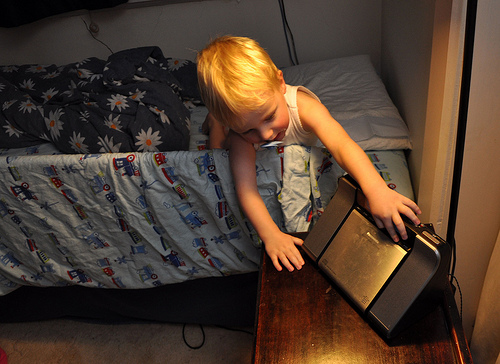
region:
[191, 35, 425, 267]
Blond haired child reaching out from bed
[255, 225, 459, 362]
Wooden night table next to the bed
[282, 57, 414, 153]
White pillow on the bed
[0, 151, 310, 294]
Sheet with train print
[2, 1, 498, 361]
room with bed in corner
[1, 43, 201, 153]
comforter with white flowers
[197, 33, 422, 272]
blonde child with extended arms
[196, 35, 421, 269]
child in white sleeveless top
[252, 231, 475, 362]
wood surface of table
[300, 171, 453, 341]
hand on electronic device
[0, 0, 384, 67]
wires hanging in front of wall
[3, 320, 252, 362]
black wire on floor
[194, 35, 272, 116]
Light blonde hair on a child's head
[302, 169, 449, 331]
A CD player on a table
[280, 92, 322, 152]
A white shirt on a child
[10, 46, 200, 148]
A gray blanket with a flower pattern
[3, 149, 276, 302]
A child's white sheet with a train pattern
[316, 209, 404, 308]
Gray cover on a CD player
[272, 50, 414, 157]
A pillow on a child's bed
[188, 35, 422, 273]
A child reaching for a CD player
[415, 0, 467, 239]
A wooden beam on a bed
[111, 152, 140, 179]
picture on white blanket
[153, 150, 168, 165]
picture on white blanket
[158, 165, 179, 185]
picture on white blanket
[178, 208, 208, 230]
picture on white blanket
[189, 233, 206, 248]
picture on white blanket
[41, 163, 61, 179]
picture on white blanket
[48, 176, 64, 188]
picture on white blanket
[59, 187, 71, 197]
picture on white blanket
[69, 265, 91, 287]
picture on white blanket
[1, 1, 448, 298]
a toddler in a crib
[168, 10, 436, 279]
the toddler is blond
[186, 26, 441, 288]
toddler has extended arms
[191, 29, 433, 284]
two arms are in front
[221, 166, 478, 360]
a radio on top a night table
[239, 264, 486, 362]
night table is brown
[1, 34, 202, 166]
a comforter with white flowers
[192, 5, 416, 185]
a white pillow behind a toddler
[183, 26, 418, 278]
toddler wears a white top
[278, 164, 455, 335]
a radio color black and silver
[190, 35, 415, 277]
little boy playing in his bed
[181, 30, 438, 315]
boy turning on the radio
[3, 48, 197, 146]
flowered comforter on the bed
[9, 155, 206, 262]
train sheet on the boys bed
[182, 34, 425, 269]
A small child in its bed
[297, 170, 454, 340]
An electronic device of some sort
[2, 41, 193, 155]
A dark blue blanket with flowers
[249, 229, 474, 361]
A wooden table sitting by a bed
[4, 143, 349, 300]
A sheet on a child's bed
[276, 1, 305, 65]
A black cable wire for something